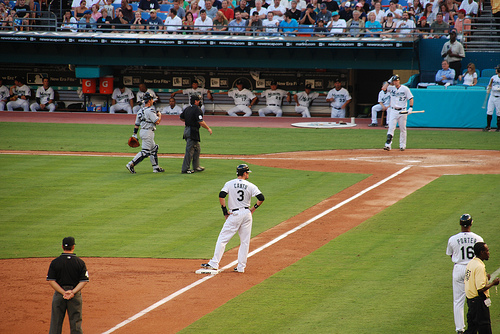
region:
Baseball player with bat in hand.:
[377, 72, 419, 152]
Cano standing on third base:
[196, 163, 263, 280]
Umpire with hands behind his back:
[44, 235, 86, 332]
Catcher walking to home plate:
[125, 88, 162, 178]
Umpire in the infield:
[178, 94, 210, 177]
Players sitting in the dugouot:
[0, 72, 348, 113]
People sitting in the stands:
[2, 0, 497, 42]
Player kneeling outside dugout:
[366, 76, 393, 130]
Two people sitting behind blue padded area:
[407, 58, 494, 130]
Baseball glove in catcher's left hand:
[126, 132, 139, 149]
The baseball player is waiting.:
[202, 162, 264, 271]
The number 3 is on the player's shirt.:
[233, 188, 245, 203]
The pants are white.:
[226, 216, 251, 230]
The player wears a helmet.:
[458, 212, 473, 224]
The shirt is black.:
[54, 259, 79, 277]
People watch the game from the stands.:
[65, 0, 425, 33]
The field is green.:
[327, 251, 420, 332]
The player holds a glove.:
[125, 130, 142, 150]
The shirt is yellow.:
[470, 262, 482, 283]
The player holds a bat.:
[397, 105, 427, 115]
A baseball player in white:
[374, 72, 426, 164]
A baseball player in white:
[191, 154, 265, 286]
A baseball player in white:
[441, 202, 481, 330]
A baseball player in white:
[481, 50, 499, 132]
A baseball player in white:
[115, 82, 168, 176]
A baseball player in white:
[323, 75, 355, 121]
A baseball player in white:
[324, 72, 362, 133]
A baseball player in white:
[261, 75, 286, 114]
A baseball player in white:
[225, 81, 253, 122]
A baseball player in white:
[109, 79, 136, 133]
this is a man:
[188, 158, 301, 294]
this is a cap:
[63, 234, 84, 249]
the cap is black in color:
[61, 233, 80, 245]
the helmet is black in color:
[241, 161, 252, 178]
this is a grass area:
[311, 235, 371, 320]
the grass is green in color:
[335, 286, 364, 308]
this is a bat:
[389, 101, 428, 118]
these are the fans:
[201, 2, 322, 14]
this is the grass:
[114, 194, 158, 209]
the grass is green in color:
[346, 267, 381, 304]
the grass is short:
[327, 245, 369, 279]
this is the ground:
[268, 252, 283, 257]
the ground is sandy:
[359, 156, 371, 161]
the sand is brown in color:
[369, 173, 381, 180]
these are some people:
[29, 12, 492, 317]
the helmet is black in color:
[239, 162, 254, 172]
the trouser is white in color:
[238, 213, 248, 224]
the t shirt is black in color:
[57, 262, 74, 275]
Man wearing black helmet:
[185, 145, 290, 282]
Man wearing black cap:
[35, 227, 98, 319]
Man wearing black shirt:
[32, 230, 104, 330]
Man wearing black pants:
[36, 228, 101, 318]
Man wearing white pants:
[201, 158, 274, 268]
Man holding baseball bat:
[371, 72, 436, 157]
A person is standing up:
[44, 235, 84, 317]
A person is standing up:
[437, 210, 469, 315]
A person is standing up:
[380, 75, 431, 169]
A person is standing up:
[483, 67, 495, 121]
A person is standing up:
[180, 95, 212, 177]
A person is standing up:
[121, 87, 166, 172]